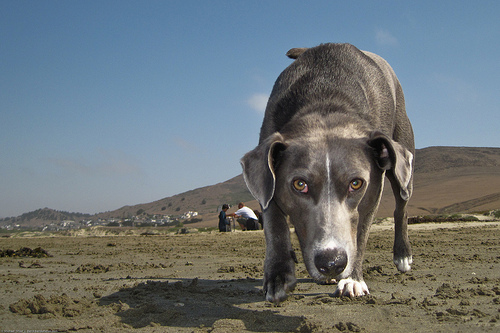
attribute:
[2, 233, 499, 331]
sand — dark gray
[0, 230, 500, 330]
dirt — brown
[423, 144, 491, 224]
hills — in the background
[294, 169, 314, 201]
eye — dog's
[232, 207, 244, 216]
sleeve — long sleeve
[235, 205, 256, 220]
shirt — white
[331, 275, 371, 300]
paw — white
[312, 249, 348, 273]
nose — black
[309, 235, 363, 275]
nose — black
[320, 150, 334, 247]
stripe — white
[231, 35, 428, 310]
dog — big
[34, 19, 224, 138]
sky — blue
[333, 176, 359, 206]
eye — dog's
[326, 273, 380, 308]
paw — white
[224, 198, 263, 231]
man — seated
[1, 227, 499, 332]
field — dirt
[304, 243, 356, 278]
nose — black